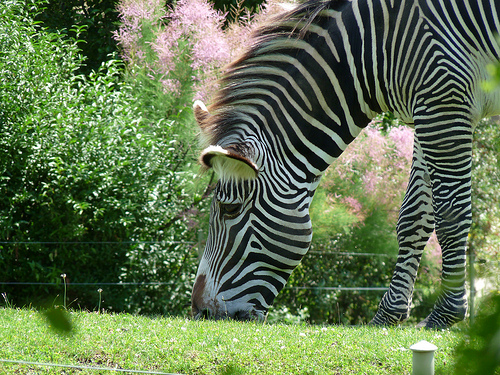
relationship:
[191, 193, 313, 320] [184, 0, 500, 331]
face of zebra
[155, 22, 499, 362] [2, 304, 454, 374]
zebra feeding on grass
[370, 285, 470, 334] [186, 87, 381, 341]
feet of zebra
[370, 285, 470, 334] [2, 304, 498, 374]
feet on field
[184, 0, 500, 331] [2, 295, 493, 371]
zebra grazing on grass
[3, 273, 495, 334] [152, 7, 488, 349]
fence surrounding zebra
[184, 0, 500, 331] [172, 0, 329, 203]
zebra has mane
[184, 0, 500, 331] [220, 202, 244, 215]
zebra has eye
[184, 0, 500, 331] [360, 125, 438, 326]
zebra has leg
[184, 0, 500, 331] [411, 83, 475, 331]
zebra has leg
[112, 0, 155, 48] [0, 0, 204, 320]
flower are on vegetation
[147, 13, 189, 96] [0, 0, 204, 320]
flowers are on vegetation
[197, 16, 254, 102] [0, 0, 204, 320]
flowers are on vegetation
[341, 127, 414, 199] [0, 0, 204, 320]
flowers are on vegetation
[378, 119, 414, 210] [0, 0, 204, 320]
flowers are on vegetation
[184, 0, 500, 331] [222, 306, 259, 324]
zebra has mouth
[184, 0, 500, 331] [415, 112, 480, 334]
zebra has leg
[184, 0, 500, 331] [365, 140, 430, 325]
zebra has leg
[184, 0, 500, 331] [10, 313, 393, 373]
zebra grazing on grass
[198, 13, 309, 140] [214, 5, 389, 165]
mane on neck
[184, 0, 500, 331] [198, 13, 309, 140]
zebra has mane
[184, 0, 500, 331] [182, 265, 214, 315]
zebra has nose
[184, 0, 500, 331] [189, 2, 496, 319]
zebra has stripes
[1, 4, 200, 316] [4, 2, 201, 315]
leaves are on bush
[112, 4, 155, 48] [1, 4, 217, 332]
flower behind bush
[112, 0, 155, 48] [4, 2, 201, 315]
flower on bush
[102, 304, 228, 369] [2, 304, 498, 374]
grass on field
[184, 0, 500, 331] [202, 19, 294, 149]
zebra has mane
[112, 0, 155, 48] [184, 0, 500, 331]
flower behind zebra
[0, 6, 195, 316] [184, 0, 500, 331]
vegetation behind zebra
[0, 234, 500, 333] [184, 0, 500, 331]
fence behind zebra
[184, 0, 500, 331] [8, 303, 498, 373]
zebra looking down at grass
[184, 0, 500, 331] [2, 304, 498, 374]
zebra on field